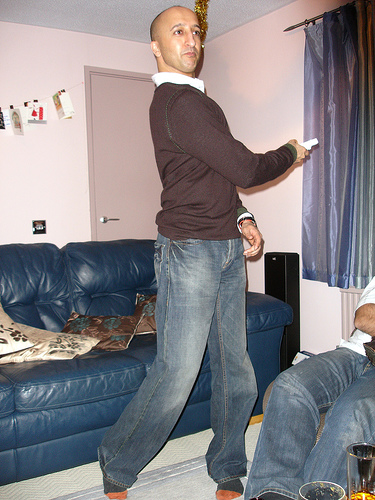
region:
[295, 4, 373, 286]
purple curtains on rod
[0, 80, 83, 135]
cards hanging on line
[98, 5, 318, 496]
man standing with game control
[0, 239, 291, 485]
front of blue leather couch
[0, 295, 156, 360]
flat pillows on couch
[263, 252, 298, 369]
black speaker on floor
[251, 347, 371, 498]
legs of sitting man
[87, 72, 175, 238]
door with silver handle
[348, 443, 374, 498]
glass with yellow liquid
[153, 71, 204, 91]
white collar of shirt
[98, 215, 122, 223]
silver door handle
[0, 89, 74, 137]
string of cards hanging on the wall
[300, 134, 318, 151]
Wii remote control in man's hand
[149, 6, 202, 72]
head of man playing Wii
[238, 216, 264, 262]
left hand of man playing Wii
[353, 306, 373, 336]
elbow of man off camera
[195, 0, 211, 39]
bit of gold garland by man's head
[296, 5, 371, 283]
shimmery blue curtains over window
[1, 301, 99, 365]
tan pillows on left side of couch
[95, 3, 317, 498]
bald man playing Wii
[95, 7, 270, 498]
Man making funny face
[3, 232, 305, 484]
Blue sofa behind man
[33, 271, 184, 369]
Two brown and blue sofa pillows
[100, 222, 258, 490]
Blue jeans on man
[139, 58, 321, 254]
Brown shirt on man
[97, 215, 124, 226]
Silver handle on door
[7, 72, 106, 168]
White flags on wall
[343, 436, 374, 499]
Small clear cup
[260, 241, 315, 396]
Black tower ac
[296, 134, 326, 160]
White wii controller in the mans hands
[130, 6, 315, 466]
man playing a wii game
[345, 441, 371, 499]
glass on the table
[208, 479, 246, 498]
orange and blue socks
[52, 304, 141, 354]
pillow on the couch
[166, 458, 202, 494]
gray rug on the floor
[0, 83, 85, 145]
cards hanging on the wall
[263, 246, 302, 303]
speaker behind the couch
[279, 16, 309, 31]
curtain rod above the window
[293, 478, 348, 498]
plastic cup on the table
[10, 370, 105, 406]
blue leather couch cushion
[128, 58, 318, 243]
he is wearing a brown shirt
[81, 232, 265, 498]
he is wearing blue jeans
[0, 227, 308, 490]
the couch is blue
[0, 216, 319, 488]
the couch is leather and blue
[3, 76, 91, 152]
greeting cards hanging on some string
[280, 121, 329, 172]
a white Wii remote control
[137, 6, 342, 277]
he is holding a Nintendo Wii controller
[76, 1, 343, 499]
he is playing a video game on the Wii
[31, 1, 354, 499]
he is playing a video game on a console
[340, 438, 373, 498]
a glass with a drink